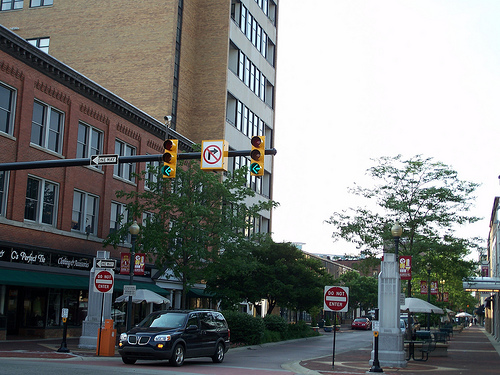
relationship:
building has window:
[3, 27, 220, 361] [29, 98, 49, 148]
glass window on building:
[29, 98, 46, 145] [0, 27, 197, 341]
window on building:
[0, 78, 20, 139] [0, 4, 280, 335]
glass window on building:
[45, 101, 70, 151] [0, 16, 200, 301]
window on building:
[113, 136, 123, 177] [0, 27, 197, 341]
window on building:
[77, 122, 104, 183] [0, 4, 280, 335]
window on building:
[23, 174, 42, 224] [3, 27, 220, 361]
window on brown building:
[21, 165, 66, 225] [0, 0, 279, 339]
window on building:
[22, 87, 85, 151] [0, 4, 280, 335]